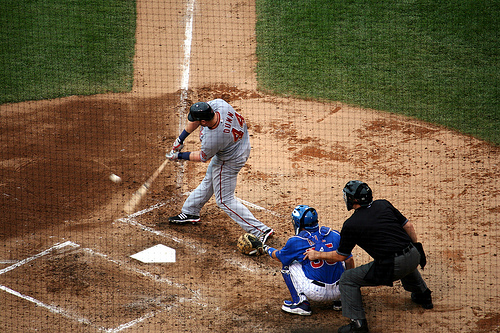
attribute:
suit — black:
[331, 201, 441, 331]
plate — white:
[129, 243, 177, 266]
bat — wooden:
[122, 142, 177, 214]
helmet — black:
[187, 102, 214, 124]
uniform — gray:
[182, 99, 276, 245]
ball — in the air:
[111, 173, 123, 184]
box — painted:
[3, 242, 204, 333]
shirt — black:
[331, 196, 433, 281]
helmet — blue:
[287, 202, 323, 230]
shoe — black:
[170, 211, 199, 225]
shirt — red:
[272, 232, 353, 282]